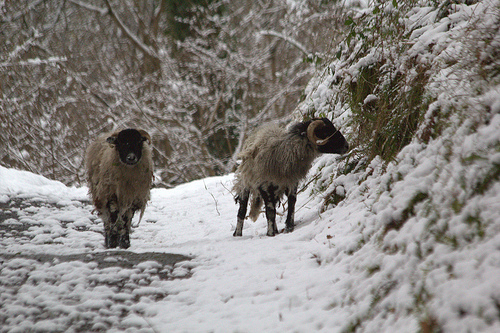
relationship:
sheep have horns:
[82, 117, 351, 250] [102, 121, 342, 148]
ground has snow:
[1, 164, 320, 331] [1, 167, 406, 332]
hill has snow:
[292, 8, 499, 332] [1, 167, 406, 332]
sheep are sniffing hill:
[82, 117, 351, 250] [292, 8, 499, 332]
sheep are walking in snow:
[82, 117, 351, 250] [1, 167, 406, 332]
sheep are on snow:
[82, 117, 351, 250] [1, 167, 406, 332]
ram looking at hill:
[234, 117, 348, 238] [292, 8, 499, 332]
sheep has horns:
[82, 117, 351, 250] [102, 121, 342, 148]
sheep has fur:
[82, 117, 351, 250] [309, 118, 352, 157]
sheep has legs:
[82, 117, 351, 250] [232, 185, 300, 235]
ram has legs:
[234, 117, 348, 238] [232, 185, 300, 235]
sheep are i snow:
[82, 117, 351, 250] [1, 167, 406, 332]